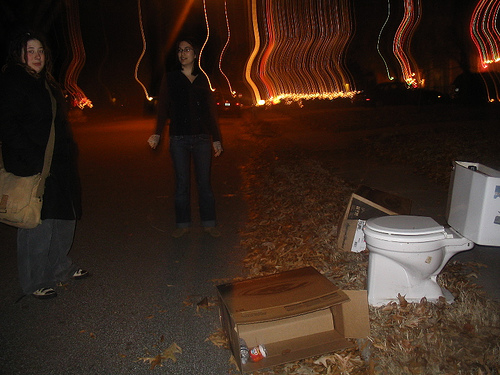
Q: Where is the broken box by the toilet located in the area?
A: Grass outside.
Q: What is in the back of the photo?
A: Waves of light in the night.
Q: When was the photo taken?
A: It is night time.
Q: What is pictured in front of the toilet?
A: A cardboard box with plastic bottles.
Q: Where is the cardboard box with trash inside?
A: In front of the toilet.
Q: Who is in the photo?
A: Two young people.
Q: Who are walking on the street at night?
A: Two women.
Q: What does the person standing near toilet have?
A: A bag.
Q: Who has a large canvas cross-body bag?
A: One of the women.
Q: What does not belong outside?
A: Toliet.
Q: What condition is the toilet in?
A: Broken.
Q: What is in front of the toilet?
A: Box.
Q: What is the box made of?
A: Cardboard.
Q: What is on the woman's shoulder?
A: Bag.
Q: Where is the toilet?
A: Trash pile.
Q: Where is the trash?
A: Side of road.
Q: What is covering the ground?
A: Leaves.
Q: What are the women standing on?
A: Road.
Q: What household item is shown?
A: Toilet.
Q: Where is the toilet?
A: Outdoors in the street.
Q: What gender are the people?
A: Female.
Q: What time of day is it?
A: Night.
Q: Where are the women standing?
A: In the road.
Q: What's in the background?
A: Lights.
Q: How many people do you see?
A: Two.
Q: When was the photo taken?
A: Night.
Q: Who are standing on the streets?
A: Women.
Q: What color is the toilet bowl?
A: White.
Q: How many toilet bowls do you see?
A: One.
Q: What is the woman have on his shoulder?
A: A messenger bag.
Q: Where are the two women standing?
A: On the road.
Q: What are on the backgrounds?
A: Lights.